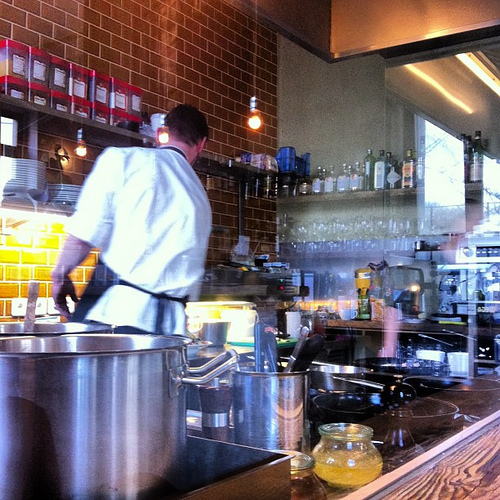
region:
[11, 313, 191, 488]
A large stainless steel pot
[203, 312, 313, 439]
A small stainless container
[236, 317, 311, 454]
A small container with utensils in it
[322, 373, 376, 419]
A frying pan on counter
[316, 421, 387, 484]
A jar with yellow liquid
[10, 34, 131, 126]
A shelf with spices on it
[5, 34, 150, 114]
Clear spice containers with red lids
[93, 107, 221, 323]
Man in a white shirt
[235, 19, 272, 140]
Light hanging near man and brick wall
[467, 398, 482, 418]
part of a table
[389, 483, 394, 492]
edge of a table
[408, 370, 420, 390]
part of a plate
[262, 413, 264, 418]
edge of a tin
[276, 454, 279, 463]
part of a table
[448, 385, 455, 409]
edge of a table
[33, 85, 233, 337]
chef cooking in kitchen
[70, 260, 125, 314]
black chef apron on man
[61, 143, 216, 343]
white chef shirt on man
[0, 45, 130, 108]
red containers of spices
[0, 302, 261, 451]
large silver pot in front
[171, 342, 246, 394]
large handle on silver pot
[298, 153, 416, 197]
bottles of oils on shelf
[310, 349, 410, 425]
black frying pans on counter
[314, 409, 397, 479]
glass container of yellow liquid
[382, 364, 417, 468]
black pepper grinder on counter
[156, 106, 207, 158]
man with short hair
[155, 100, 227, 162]
man with short dark hair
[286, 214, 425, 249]
many empty glasses in kitchen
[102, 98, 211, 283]
man in a white shirt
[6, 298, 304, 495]
many large metal pots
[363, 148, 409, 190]
bottle on a shelf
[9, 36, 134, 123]
many containers with red lids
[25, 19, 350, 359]
a worker in a restaurant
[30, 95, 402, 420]
this is kitchen area in a restaurant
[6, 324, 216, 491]
a large metal pot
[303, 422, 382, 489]
a jar with with a yellow liquid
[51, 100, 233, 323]
he worker is wearing a black apron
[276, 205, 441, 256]
glasses on a wall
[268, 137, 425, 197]
jars and bottles on a top shelf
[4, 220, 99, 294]
a yellow brick wall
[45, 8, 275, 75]
the wall is made of red bricks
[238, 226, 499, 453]
a lot of items in the kitchen